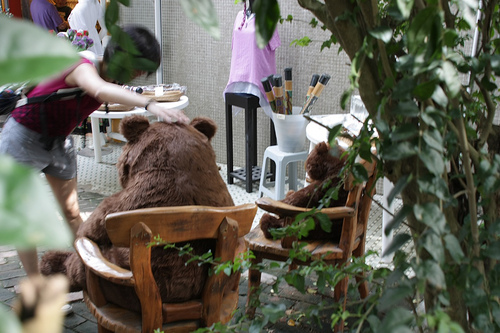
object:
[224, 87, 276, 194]
black stool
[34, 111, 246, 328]
bear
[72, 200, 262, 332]
chair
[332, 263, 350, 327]
leg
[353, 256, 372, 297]
leg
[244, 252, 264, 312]
leg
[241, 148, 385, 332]
chair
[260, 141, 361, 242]
bear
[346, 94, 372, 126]
glass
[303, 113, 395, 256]
table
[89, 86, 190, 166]
table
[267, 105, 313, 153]
white pail